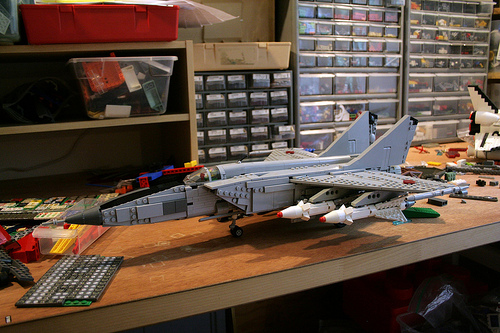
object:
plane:
[61, 108, 471, 239]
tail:
[465, 84, 500, 155]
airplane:
[469, 83, 499, 153]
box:
[68, 51, 179, 120]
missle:
[318, 200, 410, 226]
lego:
[14, 252, 125, 308]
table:
[2, 145, 499, 330]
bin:
[297, 69, 336, 98]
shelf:
[0, 43, 202, 170]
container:
[17, 0, 182, 43]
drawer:
[436, 27, 451, 45]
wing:
[291, 170, 459, 194]